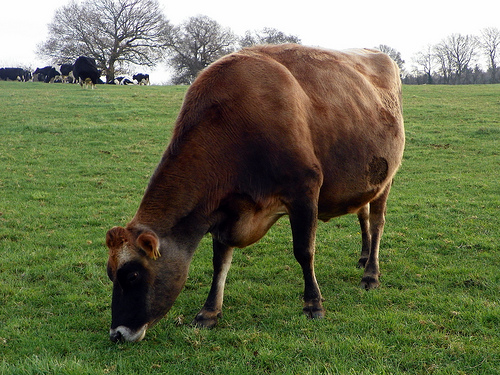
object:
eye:
[133, 271, 139, 276]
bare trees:
[37, 0, 178, 85]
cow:
[133, 73, 151, 86]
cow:
[109, 76, 137, 86]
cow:
[73, 56, 102, 90]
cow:
[32, 66, 60, 83]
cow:
[57, 64, 73, 83]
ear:
[135, 232, 159, 259]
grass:
[0, 77, 495, 375]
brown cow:
[104, 43, 407, 343]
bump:
[105, 226, 129, 249]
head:
[104, 226, 191, 343]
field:
[1, 85, 498, 374]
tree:
[168, 15, 236, 84]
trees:
[474, 27, 500, 83]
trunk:
[106, 69, 115, 84]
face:
[106, 251, 182, 343]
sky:
[0, 0, 499, 86]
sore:
[368, 156, 389, 186]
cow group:
[0, 56, 151, 90]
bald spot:
[369, 156, 389, 185]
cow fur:
[220, 53, 324, 162]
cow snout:
[109, 330, 128, 343]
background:
[0, 0, 497, 86]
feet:
[192, 310, 223, 329]